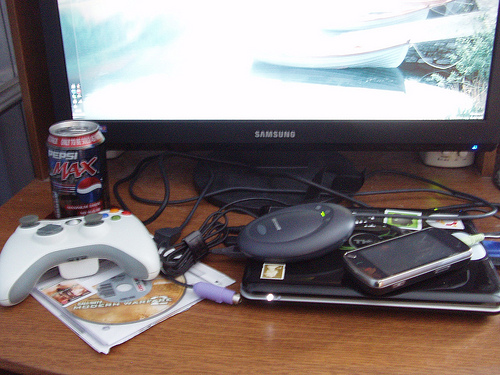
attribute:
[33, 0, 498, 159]
computer — samsung, on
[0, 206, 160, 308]
game controller — white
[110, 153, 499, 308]
wires — black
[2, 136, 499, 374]
table — brown, light brown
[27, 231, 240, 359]
video games — cds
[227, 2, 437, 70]
boat — tied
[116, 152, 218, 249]
cord — unplugged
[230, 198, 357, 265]
mouse — grey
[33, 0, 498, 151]
monitor — on, large, samsung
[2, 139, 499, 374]
desk — wooden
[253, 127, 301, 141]
samsung — brand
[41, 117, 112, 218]
soda can — aluminum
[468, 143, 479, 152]
light — on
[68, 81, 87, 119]
icons — small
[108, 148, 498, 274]
cables — black